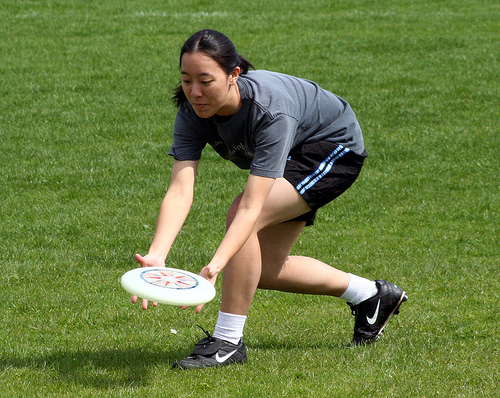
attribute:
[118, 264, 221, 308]
frisbee — large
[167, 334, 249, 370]
shoe — black, white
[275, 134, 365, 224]
shorts — black and white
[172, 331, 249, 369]
shoe — black, white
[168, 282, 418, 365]
shoes — nike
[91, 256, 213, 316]
frisbee — white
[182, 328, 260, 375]
shoes — cleat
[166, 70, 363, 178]
shirt — short, gray